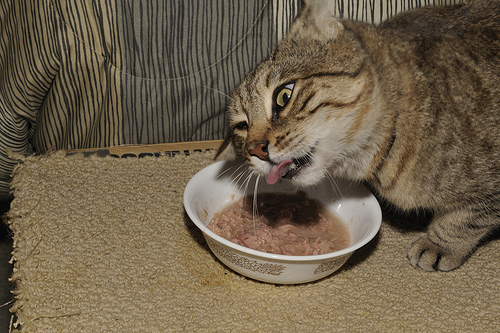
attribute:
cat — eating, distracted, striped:
[216, 0, 500, 270]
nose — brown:
[247, 141, 271, 161]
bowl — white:
[183, 157, 383, 284]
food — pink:
[200, 185, 351, 258]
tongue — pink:
[266, 159, 294, 183]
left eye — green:
[271, 80, 299, 119]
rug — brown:
[1, 145, 500, 332]